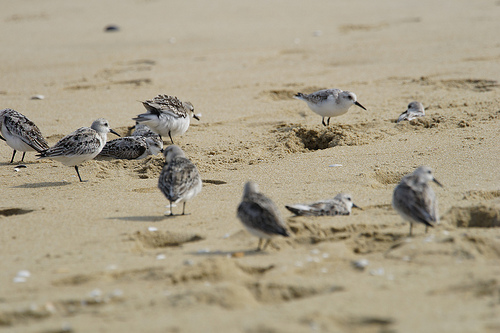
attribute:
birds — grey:
[5, 82, 464, 259]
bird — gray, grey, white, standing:
[149, 149, 205, 212]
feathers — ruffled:
[142, 87, 187, 116]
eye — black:
[100, 121, 111, 128]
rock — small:
[25, 88, 51, 106]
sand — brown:
[44, 44, 254, 88]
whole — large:
[441, 200, 497, 238]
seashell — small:
[395, 91, 439, 127]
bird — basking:
[292, 182, 363, 232]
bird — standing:
[43, 121, 116, 195]